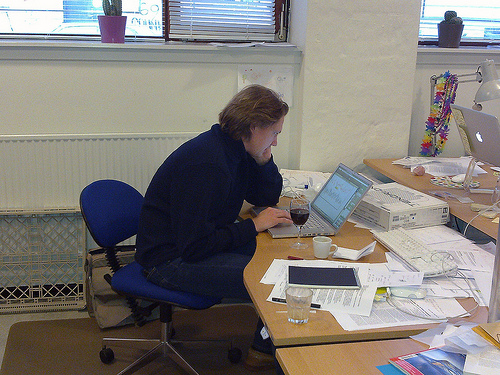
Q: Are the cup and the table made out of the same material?
A: No, the cup is made of glass and the table is made of wood.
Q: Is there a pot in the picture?
A: Yes, there is a pot.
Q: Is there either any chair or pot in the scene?
A: Yes, there is a pot.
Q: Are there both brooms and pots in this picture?
A: No, there is a pot but no brooms.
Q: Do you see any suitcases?
A: No, there are no suitcases.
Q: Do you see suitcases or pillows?
A: No, there are no suitcases or pillows.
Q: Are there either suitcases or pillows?
A: No, there are no suitcases or pillows.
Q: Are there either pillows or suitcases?
A: No, there are no suitcases or pillows.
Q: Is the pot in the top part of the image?
A: Yes, the pot is in the top of the image.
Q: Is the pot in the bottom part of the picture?
A: No, the pot is in the top of the image.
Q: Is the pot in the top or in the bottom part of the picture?
A: The pot is in the top of the image.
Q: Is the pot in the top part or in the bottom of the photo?
A: The pot is in the top of the image.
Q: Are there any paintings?
A: No, there are no paintings.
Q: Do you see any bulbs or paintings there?
A: No, there are no paintings or bulbs.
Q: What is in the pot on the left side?
A: The cactus is in the pot.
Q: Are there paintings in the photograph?
A: No, there are no paintings.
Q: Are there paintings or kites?
A: No, there are no paintings or kites.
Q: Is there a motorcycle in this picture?
A: No, there are no motorcycles.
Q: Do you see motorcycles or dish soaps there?
A: No, there are no motorcycles or dish soaps.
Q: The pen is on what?
A: The pen is on the desk.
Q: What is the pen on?
A: The pen is on the desk.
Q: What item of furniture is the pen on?
A: The pen is on the desk.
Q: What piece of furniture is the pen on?
A: The pen is on the desk.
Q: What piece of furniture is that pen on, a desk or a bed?
A: The pen is on a desk.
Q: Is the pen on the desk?
A: Yes, the pen is on the desk.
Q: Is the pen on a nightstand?
A: No, the pen is on the desk.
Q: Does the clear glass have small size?
A: Yes, the glass is small.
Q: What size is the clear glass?
A: The glass is small.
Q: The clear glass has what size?
A: The glass is small.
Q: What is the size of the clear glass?
A: The glass is small.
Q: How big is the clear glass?
A: The glass is small.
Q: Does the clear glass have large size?
A: No, the glass is small.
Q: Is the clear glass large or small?
A: The glass is small.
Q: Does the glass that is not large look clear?
A: Yes, the glass is clear.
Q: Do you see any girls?
A: No, there are no girls.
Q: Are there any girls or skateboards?
A: No, there are no girls or skateboards.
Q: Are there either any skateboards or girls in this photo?
A: No, there are no girls or skateboards.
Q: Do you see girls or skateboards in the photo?
A: No, there are no girls or skateboards.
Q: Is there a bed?
A: No, there are no beds.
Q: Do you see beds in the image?
A: No, there are no beds.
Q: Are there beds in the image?
A: No, there are no beds.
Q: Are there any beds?
A: No, there are no beds.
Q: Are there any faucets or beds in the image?
A: No, there are no beds or faucets.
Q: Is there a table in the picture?
A: Yes, there is a table.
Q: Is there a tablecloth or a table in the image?
A: Yes, there is a table.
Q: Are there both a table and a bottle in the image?
A: No, there is a table but no bottles.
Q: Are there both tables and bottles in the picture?
A: No, there is a table but no bottles.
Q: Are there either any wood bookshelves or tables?
A: Yes, there is a wood table.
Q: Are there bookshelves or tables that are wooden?
A: Yes, the table is wooden.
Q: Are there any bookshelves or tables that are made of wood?
A: Yes, the table is made of wood.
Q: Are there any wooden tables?
A: Yes, there is a wood table.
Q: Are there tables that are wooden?
A: Yes, there is a table that is wooden.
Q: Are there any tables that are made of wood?
A: Yes, there is a table that is made of wood.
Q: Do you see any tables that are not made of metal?
A: Yes, there is a table that is made of wood.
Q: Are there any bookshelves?
A: No, there are no bookshelves.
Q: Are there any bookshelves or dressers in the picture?
A: No, there are no bookshelves or dressers.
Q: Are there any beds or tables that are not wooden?
A: No, there is a table but it is wooden.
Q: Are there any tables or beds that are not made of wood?
A: No, there is a table but it is made of wood.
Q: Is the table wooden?
A: Yes, the table is wooden.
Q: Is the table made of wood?
A: Yes, the table is made of wood.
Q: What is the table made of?
A: The table is made of wood.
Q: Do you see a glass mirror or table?
A: No, there is a table but it is wooden.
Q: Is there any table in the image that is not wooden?
A: No, there is a table but it is wooden.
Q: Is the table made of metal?
A: No, the table is made of wood.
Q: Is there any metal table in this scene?
A: No, there is a table but it is made of wood.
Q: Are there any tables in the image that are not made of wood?
A: No, there is a table but it is made of wood.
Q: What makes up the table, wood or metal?
A: The table is made of wood.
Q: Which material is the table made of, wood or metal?
A: The table is made of wood.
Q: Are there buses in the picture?
A: No, there are no buses.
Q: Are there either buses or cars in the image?
A: No, there are no buses or cars.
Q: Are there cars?
A: No, there are no cars.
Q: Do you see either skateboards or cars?
A: No, there are no cars or skateboards.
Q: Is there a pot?
A: Yes, there is a pot.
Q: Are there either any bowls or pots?
A: Yes, there is a pot.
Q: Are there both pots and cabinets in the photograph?
A: No, there is a pot but no cabinets.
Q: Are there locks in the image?
A: No, there are no locks.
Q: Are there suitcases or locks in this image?
A: No, there are no locks or suitcases.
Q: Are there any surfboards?
A: No, there are no surfboards.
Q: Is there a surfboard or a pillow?
A: No, there are no surfboards or pillows.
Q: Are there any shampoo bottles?
A: No, there are no shampoo bottles.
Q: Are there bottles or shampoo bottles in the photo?
A: No, there are no shampoo bottles or bottles.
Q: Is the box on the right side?
A: Yes, the box is on the right of the image.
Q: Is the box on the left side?
A: No, the box is on the right of the image.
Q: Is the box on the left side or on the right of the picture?
A: The box is on the right of the image.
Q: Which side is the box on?
A: The box is on the right of the image.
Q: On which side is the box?
A: The box is on the right of the image.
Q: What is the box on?
A: The box is on the desk.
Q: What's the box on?
A: The box is on the desk.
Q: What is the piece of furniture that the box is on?
A: The piece of furniture is a desk.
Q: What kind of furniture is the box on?
A: The box is on the desk.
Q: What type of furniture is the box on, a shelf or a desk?
A: The box is on a desk.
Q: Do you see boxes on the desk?
A: Yes, there is a box on the desk.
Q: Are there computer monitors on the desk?
A: No, there is a box on the desk.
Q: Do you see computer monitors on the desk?
A: No, there is a box on the desk.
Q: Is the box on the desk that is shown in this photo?
A: Yes, the box is on the desk.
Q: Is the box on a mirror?
A: No, the box is on the desk.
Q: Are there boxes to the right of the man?
A: Yes, there is a box to the right of the man.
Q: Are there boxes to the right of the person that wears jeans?
A: Yes, there is a box to the right of the man.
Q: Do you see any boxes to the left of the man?
A: No, the box is to the right of the man.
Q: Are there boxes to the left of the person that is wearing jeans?
A: No, the box is to the right of the man.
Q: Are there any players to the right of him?
A: No, there is a box to the right of the man.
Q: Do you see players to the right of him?
A: No, there is a box to the right of the man.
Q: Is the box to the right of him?
A: Yes, the box is to the right of the man.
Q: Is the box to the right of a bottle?
A: No, the box is to the right of the man.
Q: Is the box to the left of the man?
A: No, the box is to the right of the man.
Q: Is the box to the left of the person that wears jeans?
A: No, the box is to the right of the man.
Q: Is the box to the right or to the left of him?
A: The box is to the right of the man.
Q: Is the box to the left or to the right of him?
A: The box is to the right of the man.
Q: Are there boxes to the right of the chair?
A: Yes, there is a box to the right of the chair.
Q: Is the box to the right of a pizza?
A: No, the box is to the right of the chair.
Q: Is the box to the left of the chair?
A: No, the box is to the right of the chair.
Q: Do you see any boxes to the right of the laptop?
A: Yes, there is a box to the right of the laptop.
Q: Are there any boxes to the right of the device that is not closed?
A: Yes, there is a box to the right of the laptop.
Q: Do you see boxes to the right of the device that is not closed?
A: Yes, there is a box to the right of the laptop.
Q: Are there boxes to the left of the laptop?
A: No, the box is to the right of the laptop.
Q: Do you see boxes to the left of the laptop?
A: No, the box is to the right of the laptop.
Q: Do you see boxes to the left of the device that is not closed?
A: No, the box is to the right of the laptop.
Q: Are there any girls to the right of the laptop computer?
A: No, there is a box to the right of the laptop computer.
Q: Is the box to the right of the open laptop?
A: Yes, the box is to the right of the laptop.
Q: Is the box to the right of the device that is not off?
A: Yes, the box is to the right of the laptop.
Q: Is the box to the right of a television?
A: No, the box is to the right of the laptop.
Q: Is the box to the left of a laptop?
A: No, the box is to the right of a laptop.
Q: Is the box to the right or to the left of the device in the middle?
A: The box is to the right of the laptop.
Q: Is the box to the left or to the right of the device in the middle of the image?
A: The box is to the right of the laptop.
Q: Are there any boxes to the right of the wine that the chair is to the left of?
A: Yes, there is a box to the right of the wine.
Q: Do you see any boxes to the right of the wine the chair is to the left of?
A: Yes, there is a box to the right of the wine.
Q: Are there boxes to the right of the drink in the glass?
A: Yes, there is a box to the right of the wine.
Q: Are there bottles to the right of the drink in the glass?
A: No, there is a box to the right of the wine.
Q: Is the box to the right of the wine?
A: Yes, the box is to the right of the wine.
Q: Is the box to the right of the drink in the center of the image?
A: Yes, the box is to the right of the wine.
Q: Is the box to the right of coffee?
A: No, the box is to the right of the wine.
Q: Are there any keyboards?
A: Yes, there is a keyboard.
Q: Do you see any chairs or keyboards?
A: Yes, there is a keyboard.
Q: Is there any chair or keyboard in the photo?
A: Yes, there is a keyboard.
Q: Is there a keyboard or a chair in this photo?
A: Yes, there is a keyboard.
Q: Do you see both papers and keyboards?
A: Yes, there are both a keyboard and papers.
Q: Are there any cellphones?
A: No, there are no cellphones.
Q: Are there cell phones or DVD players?
A: No, there are no cell phones or DVD players.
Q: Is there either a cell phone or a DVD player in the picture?
A: No, there are no cell phones or DVD players.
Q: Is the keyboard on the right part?
A: Yes, the keyboard is on the right of the image.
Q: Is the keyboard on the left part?
A: No, the keyboard is on the right of the image.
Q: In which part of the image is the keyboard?
A: The keyboard is on the right of the image.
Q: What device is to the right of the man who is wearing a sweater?
A: The device is a keyboard.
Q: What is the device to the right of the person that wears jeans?
A: The device is a keyboard.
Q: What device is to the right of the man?
A: The device is a keyboard.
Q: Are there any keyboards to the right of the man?
A: Yes, there is a keyboard to the right of the man.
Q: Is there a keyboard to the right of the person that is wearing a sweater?
A: Yes, there is a keyboard to the right of the man.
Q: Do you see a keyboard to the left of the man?
A: No, the keyboard is to the right of the man.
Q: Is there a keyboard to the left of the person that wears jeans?
A: No, the keyboard is to the right of the man.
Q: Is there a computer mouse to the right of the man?
A: No, there is a keyboard to the right of the man.